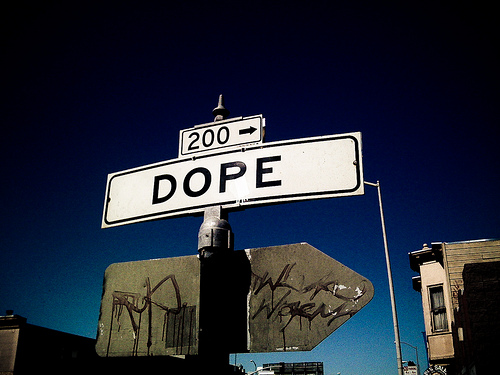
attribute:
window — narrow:
[427, 282, 449, 332]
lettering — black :
[184, 126, 254, 148]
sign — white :
[82, 95, 394, 228]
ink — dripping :
[268, 280, 365, 345]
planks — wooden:
[442, 239, 498, 314]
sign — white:
[100, 130, 363, 235]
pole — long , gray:
[376, 179, 405, 374]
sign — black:
[176, 114, 264, 159]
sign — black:
[90, 241, 375, 358]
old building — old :
[397, 226, 495, 367]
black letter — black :
[151, 174, 176, 204]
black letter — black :
[182, 167, 211, 198]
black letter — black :
[218, 161, 246, 193]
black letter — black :
[256, 155, 283, 188]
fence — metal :
[419, 246, 498, 373]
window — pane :
[421, 277, 453, 334]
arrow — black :
[236, 124, 257, 139]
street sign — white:
[113, 130, 372, 227]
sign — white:
[76, 100, 391, 247]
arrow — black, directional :
[232, 118, 260, 140]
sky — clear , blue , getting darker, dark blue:
[5, 0, 496, 374]